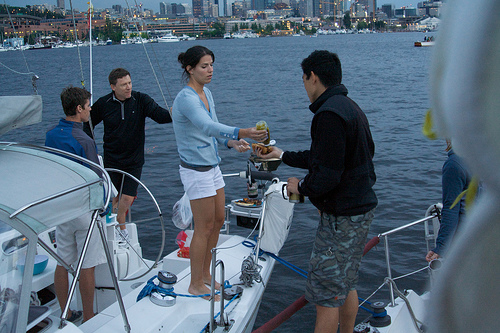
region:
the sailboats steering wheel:
[103, 164, 166, 284]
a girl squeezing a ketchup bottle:
[171, 43, 272, 143]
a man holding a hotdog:
[248, 49, 375, 166]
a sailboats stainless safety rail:
[366, 204, 446, 316]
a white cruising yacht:
[156, 32, 182, 44]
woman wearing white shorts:
[164, 47, 254, 302]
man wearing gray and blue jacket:
[51, 84, 118, 319]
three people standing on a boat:
[46, 42, 245, 310]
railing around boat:
[255, 194, 465, 332]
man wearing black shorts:
[97, 69, 172, 215]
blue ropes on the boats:
[130, 239, 379, 326]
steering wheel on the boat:
[99, 162, 167, 285]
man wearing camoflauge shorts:
[267, 48, 375, 313]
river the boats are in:
[7, 45, 461, 309]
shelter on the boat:
[2, 133, 137, 330]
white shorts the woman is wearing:
[174, 163, 229, 203]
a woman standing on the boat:
[163, 41, 273, 306]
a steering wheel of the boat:
[103, 162, 169, 283]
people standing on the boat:
[38, 43, 275, 312]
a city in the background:
[2, 0, 434, 50]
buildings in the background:
[151, 0, 436, 21]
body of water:
[8, 34, 428, 110]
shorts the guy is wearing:
[302, 210, 378, 312]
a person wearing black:
[81, 63, 172, 235]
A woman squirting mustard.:
[176, 43, 271, 301]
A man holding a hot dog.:
[249, 51, 379, 331]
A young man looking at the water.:
[41, 86, 105, 321]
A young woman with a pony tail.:
[170, 46, 267, 302]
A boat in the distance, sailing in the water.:
[412, 26, 437, 51]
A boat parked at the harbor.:
[0, 142, 293, 332]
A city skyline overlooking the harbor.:
[3, 0, 479, 49]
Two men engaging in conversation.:
[46, 67, 173, 319]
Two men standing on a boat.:
[42, 68, 173, 319]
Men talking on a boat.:
[55, 67, 169, 151]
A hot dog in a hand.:
[249, 139, 284, 161]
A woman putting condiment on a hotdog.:
[169, 42, 276, 304]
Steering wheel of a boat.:
[107, 170, 167, 274]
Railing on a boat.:
[371, 219, 424, 301]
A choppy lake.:
[220, 38, 304, 119]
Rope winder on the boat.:
[132, 268, 182, 308]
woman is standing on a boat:
[173, 46, 270, 298]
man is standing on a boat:
[256, 49, 379, 330]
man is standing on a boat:
[83, 68, 174, 227]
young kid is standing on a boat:
[45, 87, 99, 322]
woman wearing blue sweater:
[169, 32, 255, 319]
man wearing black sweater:
[282, 38, 385, 331]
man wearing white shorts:
[50, 78, 130, 323]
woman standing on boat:
[165, 31, 245, 320]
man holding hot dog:
[247, 25, 381, 302]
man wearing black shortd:
[81, 53, 176, 243]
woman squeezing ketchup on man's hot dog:
[160, 38, 292, 282]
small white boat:
[6, 105, 288, 329]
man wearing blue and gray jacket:
[38, 84, 120, 312]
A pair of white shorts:
[175, 157, 233, 204]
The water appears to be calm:
[0, 25, 447, 330]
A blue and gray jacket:
[35, 111, 106, 181]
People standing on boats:
[0, 37, 486, 327]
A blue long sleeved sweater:
[161, 80, 242, 170]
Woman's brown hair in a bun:
[171, 36, 218, 86]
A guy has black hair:
[292, 42, 347, 104]